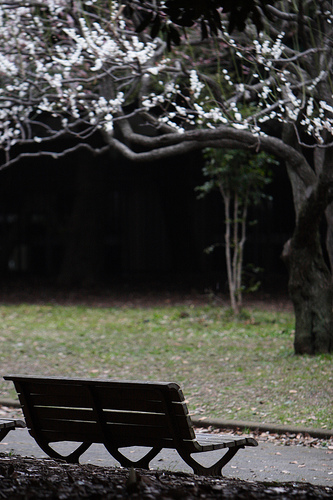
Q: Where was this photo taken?
A: In the park.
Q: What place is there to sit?
A: The bench.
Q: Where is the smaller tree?
A: By the larger tree.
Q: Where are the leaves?
A: On the ground.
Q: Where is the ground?
A: Under the tree.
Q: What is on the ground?
A: The elaves.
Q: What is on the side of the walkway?
A: A bench.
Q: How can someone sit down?
A: On the bench.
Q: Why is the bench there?
A: To rest.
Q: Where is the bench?
A: By the walkway.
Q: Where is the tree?
A: Across the walkway.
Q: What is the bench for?
A: Sitting on.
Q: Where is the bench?
A: At a park.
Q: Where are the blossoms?
A: On the tree.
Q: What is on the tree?
A: Blossoms.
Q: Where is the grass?
A: On the ground.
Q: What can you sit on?
A: The bench.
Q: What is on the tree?
A: Flowers.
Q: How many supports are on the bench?
A: Three.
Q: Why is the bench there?
A: To sit.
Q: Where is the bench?
A: Near the path.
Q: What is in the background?
A: Tree.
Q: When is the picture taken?
A: Night time.